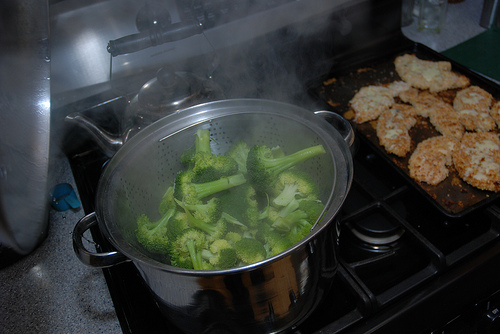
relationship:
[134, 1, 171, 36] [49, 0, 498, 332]
button to turn stove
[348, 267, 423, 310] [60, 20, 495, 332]
part of top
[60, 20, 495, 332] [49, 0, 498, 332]
top of stove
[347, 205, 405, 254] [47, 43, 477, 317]
burner on stove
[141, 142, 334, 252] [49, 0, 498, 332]
broccoli being cooked on stove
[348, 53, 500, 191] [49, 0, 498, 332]
breaded meat on stove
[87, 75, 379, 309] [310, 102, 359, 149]
cook pot has handle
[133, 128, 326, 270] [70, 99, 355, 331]
broccoli in pot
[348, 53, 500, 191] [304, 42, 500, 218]
breaded meat on pan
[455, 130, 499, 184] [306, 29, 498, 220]
breaded meat on tray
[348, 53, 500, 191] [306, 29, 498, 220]
breaded meat on tray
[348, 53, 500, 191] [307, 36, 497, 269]
breaded meat on tray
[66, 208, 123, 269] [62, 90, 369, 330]
handle on pot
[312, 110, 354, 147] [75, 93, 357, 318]
handle on pot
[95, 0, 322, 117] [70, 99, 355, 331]
smoke over pot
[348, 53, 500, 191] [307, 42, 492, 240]
breaded meat on tray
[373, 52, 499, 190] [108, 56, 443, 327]
food cooking on stove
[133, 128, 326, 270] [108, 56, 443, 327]
broccoli cooking on stove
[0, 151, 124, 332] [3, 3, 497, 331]
counter top in kitchen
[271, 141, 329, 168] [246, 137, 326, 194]
stem on broccoli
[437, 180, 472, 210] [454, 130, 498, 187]
crumbs from nugget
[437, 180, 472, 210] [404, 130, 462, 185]
crumbs from nugget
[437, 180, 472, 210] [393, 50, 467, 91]
crumbs from nugget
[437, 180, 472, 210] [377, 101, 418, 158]
crumbs from nugget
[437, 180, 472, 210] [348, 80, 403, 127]
crumbs from nugget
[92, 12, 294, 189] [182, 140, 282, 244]
smoke caused by broccoli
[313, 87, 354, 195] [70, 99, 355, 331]
handle on pot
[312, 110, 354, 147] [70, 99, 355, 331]
handle of pot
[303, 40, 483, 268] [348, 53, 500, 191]
pan of breaded meat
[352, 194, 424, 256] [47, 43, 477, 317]
burner of stove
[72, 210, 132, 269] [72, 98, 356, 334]
handle of cook pot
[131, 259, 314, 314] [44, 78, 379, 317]
reflection on pot